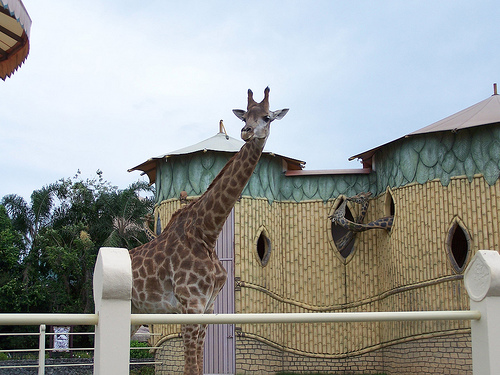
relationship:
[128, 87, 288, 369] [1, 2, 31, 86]
giraffe looking at item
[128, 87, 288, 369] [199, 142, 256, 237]
giraffe has neck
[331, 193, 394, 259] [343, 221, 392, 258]
giraffes have necks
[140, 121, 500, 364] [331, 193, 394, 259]
house has animals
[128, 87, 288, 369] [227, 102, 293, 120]
giraffe has ear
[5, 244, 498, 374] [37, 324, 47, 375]
fence has post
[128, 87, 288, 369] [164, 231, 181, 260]
giraffe has spots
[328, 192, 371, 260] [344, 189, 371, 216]
giraffe has head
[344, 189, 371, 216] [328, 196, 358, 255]
head sticking out of window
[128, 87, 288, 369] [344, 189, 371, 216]
giraffe has head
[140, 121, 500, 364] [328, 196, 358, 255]
building has window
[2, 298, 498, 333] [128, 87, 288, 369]
railing in front of giraffe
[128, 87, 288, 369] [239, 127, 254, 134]
giraffe has nose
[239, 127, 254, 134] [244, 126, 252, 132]
nose has holes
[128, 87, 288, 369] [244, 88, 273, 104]
giraffe has horns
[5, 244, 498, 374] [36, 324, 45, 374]
fence has post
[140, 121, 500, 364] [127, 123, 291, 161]
building has roof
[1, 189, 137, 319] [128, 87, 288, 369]
trees behind giraffe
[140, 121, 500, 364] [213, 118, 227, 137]
building has tip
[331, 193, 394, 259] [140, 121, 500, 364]
giraffes in house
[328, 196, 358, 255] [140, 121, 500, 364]
window in house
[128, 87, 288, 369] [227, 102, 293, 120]
giraffe has ears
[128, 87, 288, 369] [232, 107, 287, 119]
giraffe has ears